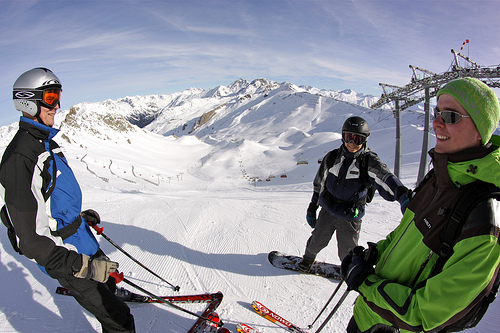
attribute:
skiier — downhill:
[1, 65, 161, 330]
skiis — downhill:
[232, 300, 321, 330]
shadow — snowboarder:
[81, 213, 325, 280]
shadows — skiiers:
[5, 200, 244, 330]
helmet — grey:
[10, 65, 62, 117]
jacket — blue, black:
[1, 115, 111, 295]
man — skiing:
[3, 50, 213, 330]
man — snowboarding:
[289, 109, 413, 301]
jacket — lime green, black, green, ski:
[336, 71, 498, 330]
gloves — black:
[336, 243, 375, 293]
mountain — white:
[76, 80, 288, 221]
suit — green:
[323, 170, 466, 328]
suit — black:
[305, 135, 403, 249]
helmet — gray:
[1, 62, 66, 129]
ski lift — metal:
[374, 64, 444, 114]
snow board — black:
[265, 244, 366, 294]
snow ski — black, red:
[112, 282, 239, 311]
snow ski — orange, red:
[238, 280, 292, 329]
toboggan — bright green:
[416, 77, 497, 137]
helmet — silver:
[8, 66, 44, 115]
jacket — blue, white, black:
[1, 130, 102, 280]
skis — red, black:
[119, 266, 228, 313]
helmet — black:
[327, 106, 383, 173]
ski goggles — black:
[335, 130, 365, 150]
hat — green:
[445, 85, 498, 139]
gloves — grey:
[67, 205, 127, 290]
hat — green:
[428, 68, 498, 149]